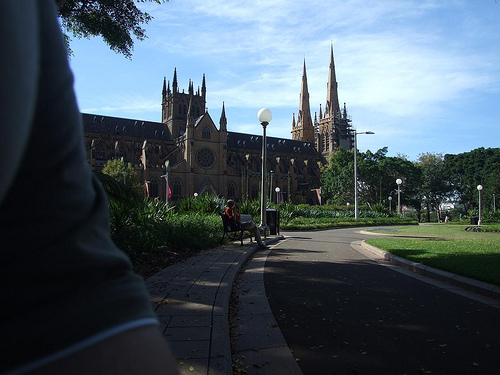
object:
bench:
[219, 210, 270, 246]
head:
[226, 199, 236, 208]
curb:
[143, 232, 277, 372]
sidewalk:
[143, 221, 392, 373]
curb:
[357, 224, 484, 329]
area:
[363, 206, 500, 370]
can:
[266, 209, 278, 233]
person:
[0, 3, 186, 375]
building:
[76, 41, 419, 205]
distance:
[16, 46, 484, 176]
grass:
[371, 218, 500, 285]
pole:
[257, 122, 269, 235]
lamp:
[255, 106, 273, 123]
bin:
[265, 208, 280, 235]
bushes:
[4, 157, 261, 263]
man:
[218, 198, 272, 249]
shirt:
[222, 206, 242, 230]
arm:
[226, 208, 234, 218]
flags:
[124, 172, 173, 204]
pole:
[162, 171, 167, 221]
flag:
[306, 188, 326, 207]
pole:
[352, 130, 359, 219]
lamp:
[255, 108, 273, 238]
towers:
[287, 41, 358, 210]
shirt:
[0, 2, 176, 375]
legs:
[240, 220, 265, 248]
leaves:
[228, 250, 255, 368]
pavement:
[230, 211, 490, 371]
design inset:
[194, 144, 219, 170]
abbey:
[181, 101, 229, 196]